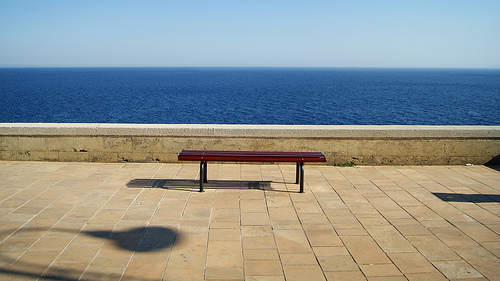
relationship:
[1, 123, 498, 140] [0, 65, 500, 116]
concrete wall near beach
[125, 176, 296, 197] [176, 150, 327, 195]
shadow of bench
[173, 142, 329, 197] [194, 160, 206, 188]
bench with leg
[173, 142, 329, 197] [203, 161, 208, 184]
bench with leg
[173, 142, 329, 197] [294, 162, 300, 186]
bench with leg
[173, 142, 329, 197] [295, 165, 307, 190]
bench with leg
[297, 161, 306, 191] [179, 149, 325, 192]
leg supporting bench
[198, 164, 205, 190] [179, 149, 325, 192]
leg supporting bench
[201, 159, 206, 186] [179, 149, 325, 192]
leg supporting bench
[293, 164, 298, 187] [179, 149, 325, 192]
leg supporting bench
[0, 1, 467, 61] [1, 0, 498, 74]
clouds in blue sky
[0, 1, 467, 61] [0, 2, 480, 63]
clouds in sky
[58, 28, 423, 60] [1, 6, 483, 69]
clouds in sky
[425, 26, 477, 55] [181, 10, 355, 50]
white clouds in blue sky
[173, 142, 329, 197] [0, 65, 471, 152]
bench at beach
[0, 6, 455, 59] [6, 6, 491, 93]
clouds in sky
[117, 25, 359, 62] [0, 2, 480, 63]
clouds in sky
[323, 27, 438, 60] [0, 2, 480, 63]
clouds in sky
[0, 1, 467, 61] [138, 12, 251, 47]
clouds in sky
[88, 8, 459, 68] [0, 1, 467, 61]
sky with clouds